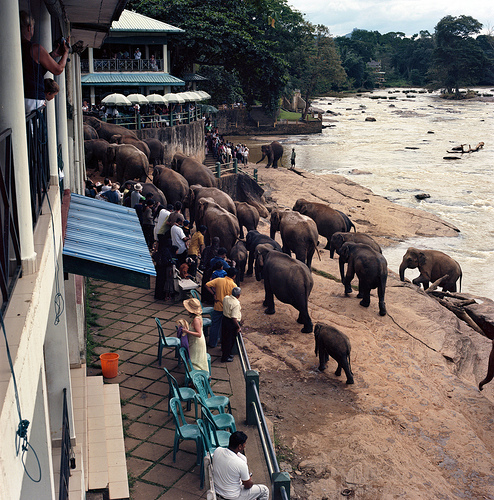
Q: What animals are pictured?
A: Elephants.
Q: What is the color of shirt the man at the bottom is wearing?
A: White.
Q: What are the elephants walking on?
A: Rocks.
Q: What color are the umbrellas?
A: White.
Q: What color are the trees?
A: Green.